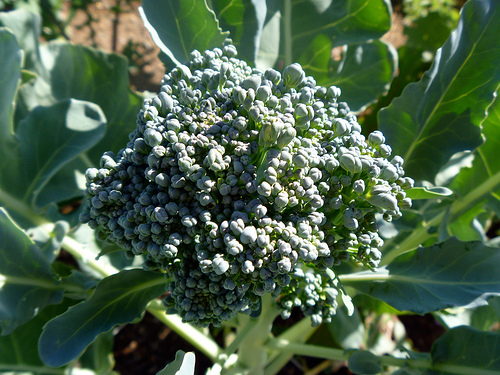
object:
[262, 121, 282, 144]
bud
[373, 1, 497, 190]
leaf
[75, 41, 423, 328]
brocooli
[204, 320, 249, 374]
stalk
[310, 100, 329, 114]
seedling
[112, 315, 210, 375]
dirt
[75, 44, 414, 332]
head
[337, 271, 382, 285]
stem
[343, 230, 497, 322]
leaf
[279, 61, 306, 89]
florets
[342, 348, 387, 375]
leaf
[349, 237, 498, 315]
branch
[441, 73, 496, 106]
vein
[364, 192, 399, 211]
flower bud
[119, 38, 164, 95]
shadow